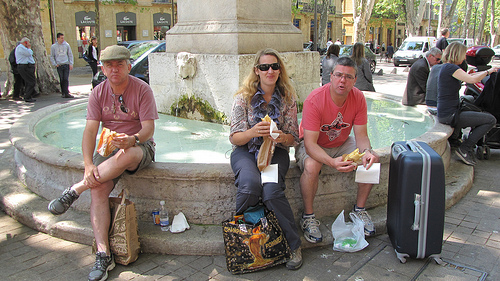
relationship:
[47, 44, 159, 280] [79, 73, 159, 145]
man wearing shirt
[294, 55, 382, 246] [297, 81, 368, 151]
nan wearing shirt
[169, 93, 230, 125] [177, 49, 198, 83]
algae below lion head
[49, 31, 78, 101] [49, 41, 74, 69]
man wearing shirt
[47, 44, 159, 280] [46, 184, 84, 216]
man wearing shoe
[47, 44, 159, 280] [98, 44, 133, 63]
man wearing cap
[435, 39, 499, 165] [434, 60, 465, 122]
woman wearing shirt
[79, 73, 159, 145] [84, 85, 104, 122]
shirt has sleeve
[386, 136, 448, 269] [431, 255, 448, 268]
suitcase has wheel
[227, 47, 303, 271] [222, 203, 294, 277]
woman has bag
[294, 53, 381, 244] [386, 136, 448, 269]
man has suitcase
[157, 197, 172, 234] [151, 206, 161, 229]
bottle beside can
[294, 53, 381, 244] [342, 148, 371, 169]
man eating sandwich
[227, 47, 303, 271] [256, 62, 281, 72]
woman wearing sunglasses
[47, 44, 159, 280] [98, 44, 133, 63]
man wearing hat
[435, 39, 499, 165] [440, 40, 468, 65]
woman has hair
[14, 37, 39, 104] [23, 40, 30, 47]
man has phone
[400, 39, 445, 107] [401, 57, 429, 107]
man wearing suit